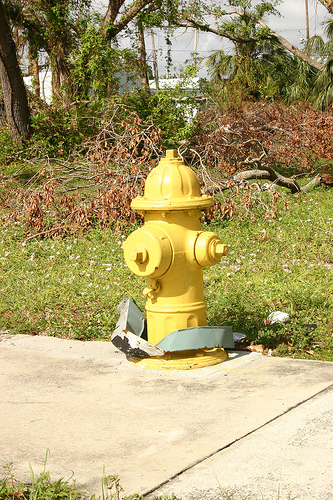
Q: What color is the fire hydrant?
A: Yellow.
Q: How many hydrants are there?
A: 1.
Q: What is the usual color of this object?
A: Red.